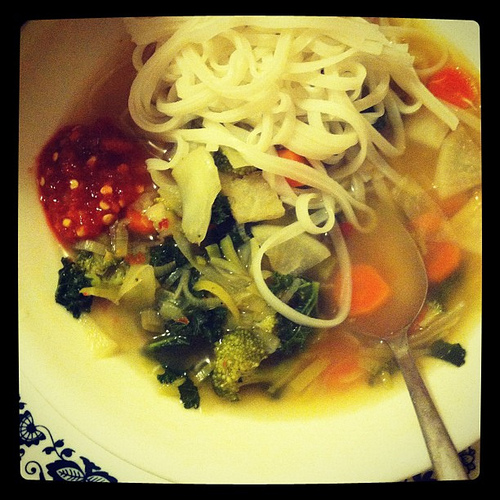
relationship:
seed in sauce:
[68, 176, 79, 189] [28, 115, 158, 247]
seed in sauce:
[100, 181, 114, 195] [28, 115, 158, 247]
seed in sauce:
[86, 152, 98, 166] [28, 115, 158, 247]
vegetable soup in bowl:
[55, 19, 481, 417] [20, 17, 484, 483]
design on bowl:
[21, 395, 120, 486] [20, 17, 484, 483]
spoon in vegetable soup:
[325, 197, 470, 482] [55, 19, 481, 417]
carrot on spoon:
[333, 263, 392, 316] [325, 197, 470, 482]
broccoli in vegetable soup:
[211, 328, 276, 404] [55, 19, 481, 417]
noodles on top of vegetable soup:
[118, 18, 461, 328] [55, 19, 481, 417]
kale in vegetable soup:
[54, 257, 93, 318] [55, 19, 481, 417]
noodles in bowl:
[118, 18, 461, 328] [20, 17, 484, 483]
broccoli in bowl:
[211, 328, 276, 404] [20, 17, 484, 483]